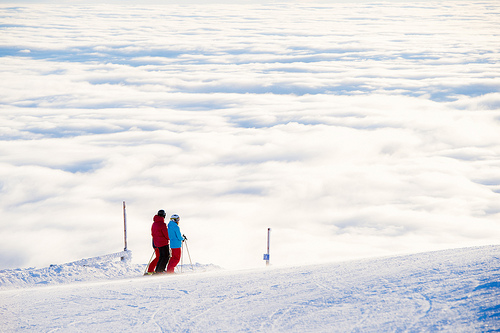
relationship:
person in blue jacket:
[166, 213, 185, 274] [166, 219, 186, 248]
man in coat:
[143, 203, 176, 268] [148, 214, 176, 247]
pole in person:
[181, 237, 195, 271] [166, 213, 185, 274]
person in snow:
[166, 213, 185, 274] [273, 272, 434, 322]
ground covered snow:
[116, 276, 488, 301] [163, 274, 423, 329]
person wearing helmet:
[166, 213, 185, 274] [167, 209, 183, 225]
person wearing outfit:
[166, 213, 185, 274] [148, 212, 188, 245]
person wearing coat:
[166, 213, 185, 274] [150, 214, 171, 248]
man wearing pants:
[150, 209, 171, 274] [154, 243, 170, 273]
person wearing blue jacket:
[166, 213, 185, 274] [166, 219, 186, 248]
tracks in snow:
[276, 262, 499, 331] [0, 243, 497, 331]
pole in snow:
[265, 225, 276, 266] [0, 232, 484, 322]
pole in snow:
[120, 198, 135, 253] [0, 232, 484, 322]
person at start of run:
[166, 213, 185, 274] [286, 243, 424, 330]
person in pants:
[166, 213, 185, 274] [159, 248, 184, 275]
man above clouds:
[150, 209, 171, 274] [172, 60, 412, 207]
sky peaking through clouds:
[37, 52, 97, 72] [1, 1, 498, 252]